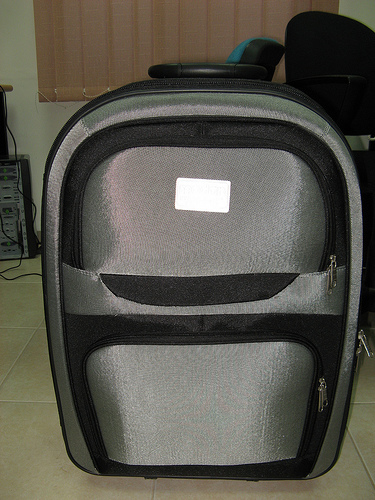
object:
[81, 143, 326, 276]
pocket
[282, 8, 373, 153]
chair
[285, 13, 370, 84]
back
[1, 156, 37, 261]
computer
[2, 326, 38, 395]
tile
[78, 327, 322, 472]
lower pocket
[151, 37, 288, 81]
chair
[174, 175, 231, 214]
patch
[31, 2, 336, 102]
blinds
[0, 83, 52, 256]
corner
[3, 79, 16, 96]
table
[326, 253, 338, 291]
metal zipper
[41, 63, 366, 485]
bag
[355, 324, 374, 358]
zipper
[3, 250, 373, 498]
floor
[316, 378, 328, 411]
zipper